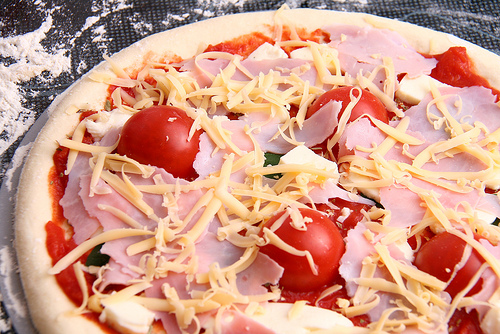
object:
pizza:
[10, 3, 499, 328]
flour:
[0, 1, 499, 192]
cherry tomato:
[112, 102, 209, 182]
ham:
[340, 24, 442, 77]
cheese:
[107, 59, 296, 103]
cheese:
[93, 292, 156, 332]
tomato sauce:
[430, 47, 500, 106]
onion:
[85, 243, 106, 263]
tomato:
[254, 206, 350, 295]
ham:
[387, 87, 499, 176]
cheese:
[281, 141, 340, 176]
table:
[0, 1, 500, 187]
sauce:
[44, 219, 95, 301]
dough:
[11, 101, 60, 326]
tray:
[4, 79, 41, 332]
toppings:
[59, 26, 499, 328]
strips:
[149, 67, 313, 104]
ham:
[80, 173, 283, 330]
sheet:
[2, 81, 25, 328]